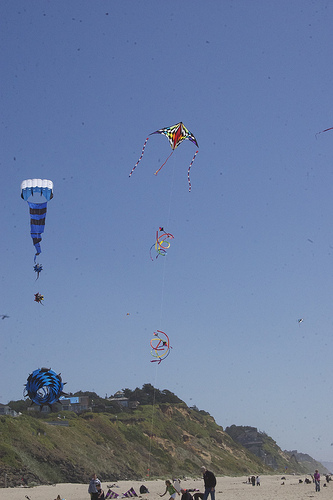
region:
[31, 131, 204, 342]
Kites are flying in the sky.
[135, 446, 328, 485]
People on the beach.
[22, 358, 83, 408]
A blue and black kite above the hill.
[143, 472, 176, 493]
A girl flying a kite.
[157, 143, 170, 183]
The tail hanging from the kite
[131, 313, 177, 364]
The kite is colorful.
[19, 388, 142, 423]
A house on top of the hill.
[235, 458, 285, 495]
People walking on the beach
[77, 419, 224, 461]
The hill is rocky and grassy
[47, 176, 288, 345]
The sky is clear and blue.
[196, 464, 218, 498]
man wearing black shirt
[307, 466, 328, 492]
woman wearing purple shirt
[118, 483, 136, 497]
purple kite in the sand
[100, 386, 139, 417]
house on the hill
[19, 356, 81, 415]
huge blue and black kite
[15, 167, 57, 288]
blue, black, and white kite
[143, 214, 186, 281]
multi color spiral kite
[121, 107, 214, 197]
kite with different colors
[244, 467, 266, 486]
people walking on the beach